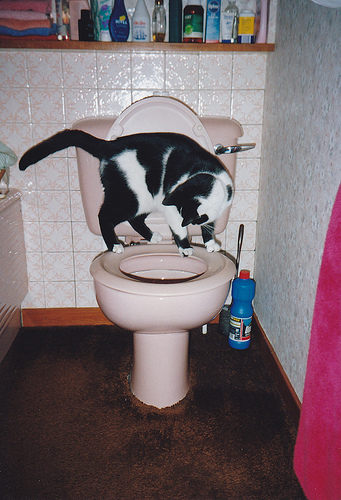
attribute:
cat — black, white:
[20, 125, 236, 257]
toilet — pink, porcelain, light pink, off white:
[75, 117, 238, 410]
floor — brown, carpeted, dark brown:
[1, 323, 307, 498]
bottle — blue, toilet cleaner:
[230, 269, 256, 351]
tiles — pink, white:
[5, 26, 271, 314]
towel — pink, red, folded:
[288, 174, 338, 499]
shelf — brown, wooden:
[3, 37, 276, 55]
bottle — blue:
[110, 0, 130, 41]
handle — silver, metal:
[216, 143, 256, 155]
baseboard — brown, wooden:
[21, 305, 304, 419]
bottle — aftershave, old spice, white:
[134, 0, 150, 44]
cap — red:
[240, 269, 252, 281]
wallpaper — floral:
[253, 4, 340, 407]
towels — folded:
[0, 0, 60, 39]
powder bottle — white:
[236, 9, 260, 46]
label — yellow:
[237, 15, 256, 36]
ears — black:
[163, 195, 197, 227]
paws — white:
[100, 233, 222, 258]